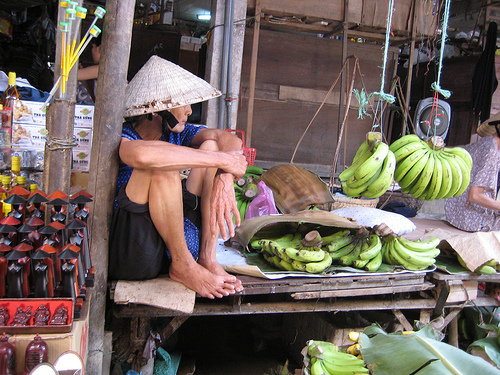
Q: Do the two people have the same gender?
A: No, they are both male and female.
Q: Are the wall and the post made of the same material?
A: Yes, both the wall and the post are made of wood.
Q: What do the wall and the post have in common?
A: The material, both the wall and the post are wooden.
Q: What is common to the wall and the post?
A: The material, both the wall and the post are wooden.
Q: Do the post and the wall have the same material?
A: Yes, both the post and the wall are made of wood.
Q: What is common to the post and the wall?
A: The material, both the post and the wall are wooden.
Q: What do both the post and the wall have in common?
A: The material, both the post and the wall are wooden.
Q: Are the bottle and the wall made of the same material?
A: No, the bottle is made of glass and the wall is made of wood.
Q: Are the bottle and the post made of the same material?
A: No, the bottle is made of glass and the post is made of wood.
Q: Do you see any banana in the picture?
A: Yes, there are bananas.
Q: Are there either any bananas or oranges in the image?
A: Yes, there are bananas.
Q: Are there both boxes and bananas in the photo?
A: Yes, there are both bananas and a box.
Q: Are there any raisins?
A: No, there are no raisins.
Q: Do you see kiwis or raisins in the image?
A: No, there are no raisins or kiwis.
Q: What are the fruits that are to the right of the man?
A: The fruits are bananas.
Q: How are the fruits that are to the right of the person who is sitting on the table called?
A: The fruits are bananas.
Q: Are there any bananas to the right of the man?
A: Yes, there are bananas to the right of the man.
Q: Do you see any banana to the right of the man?
A: Yes, there are bananas to the right of the man.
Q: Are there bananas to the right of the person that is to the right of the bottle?
A: Yes, there are bananas to the right of the man.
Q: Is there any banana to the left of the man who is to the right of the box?
A: No, the bananas are to the right of the man.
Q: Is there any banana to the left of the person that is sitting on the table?
A: No, the bananas are to the right of the man.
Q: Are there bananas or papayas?
A: Yes, there are bananas.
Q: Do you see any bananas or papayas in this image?
A: Yes, there are bananas.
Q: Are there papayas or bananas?
A: Yes, there are bananas.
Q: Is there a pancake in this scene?
A: No, there are no pancakes.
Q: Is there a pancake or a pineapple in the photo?
A: No, there are no pancakes or pineapples.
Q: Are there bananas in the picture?
A: Yes, there are bananas.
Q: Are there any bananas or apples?
A: Yes, there are bananas.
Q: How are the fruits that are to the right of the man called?
A: The fruits are bananas.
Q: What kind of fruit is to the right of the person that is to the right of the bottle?
A: The fruits are bananas.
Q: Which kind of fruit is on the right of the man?
A: The fruits are bananas.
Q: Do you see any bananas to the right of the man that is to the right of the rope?
A: Yes, there are bananas to the right of the man.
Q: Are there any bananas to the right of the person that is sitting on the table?
A: Yes, there are bananas to the right of the man.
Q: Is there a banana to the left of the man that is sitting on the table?
A: No, the bananas are to the right of the man.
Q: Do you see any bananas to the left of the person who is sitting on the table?
A: No, the bananas are to the right of the man.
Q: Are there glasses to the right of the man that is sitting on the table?
A: No, there are bananas to the right of the man.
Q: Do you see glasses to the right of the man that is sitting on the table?
A: No, there are bananas to the right of the man.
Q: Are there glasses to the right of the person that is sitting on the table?
A: No, there are bananas to the right of the man.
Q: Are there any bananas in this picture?
A: Yes, there are bananas.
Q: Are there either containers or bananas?
A: Yes, there are bananas.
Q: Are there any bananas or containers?
A: Yes, there are bananas.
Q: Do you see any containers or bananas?
A: Yes, there are bananas.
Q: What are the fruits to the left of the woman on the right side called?
A: The fruits are bananas.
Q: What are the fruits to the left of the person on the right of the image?
A: The fruits are bananas.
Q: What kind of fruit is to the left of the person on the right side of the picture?
A: The fruits are bananas.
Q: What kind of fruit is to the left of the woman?
A: The fruits are bananas.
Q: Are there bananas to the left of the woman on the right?
A: Yes, there are bananas to the left of the woman.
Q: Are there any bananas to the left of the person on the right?
A: Yes, there are bananas to the left of the woman.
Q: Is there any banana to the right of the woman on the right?
A: No, the bananas are to the left of the woman.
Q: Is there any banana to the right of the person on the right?
A: No, the bananas are to the left of the woman.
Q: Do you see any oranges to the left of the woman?
A: No, there are bananas to the left of the woman.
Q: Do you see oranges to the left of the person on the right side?
A: No, there are bananas to the left of the woman.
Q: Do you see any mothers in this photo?
A: No, there are no mothers.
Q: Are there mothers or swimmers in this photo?
A: No, there are no mothers or swimmers.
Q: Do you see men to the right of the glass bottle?
A: Yes, there is a man to the right of the bottle.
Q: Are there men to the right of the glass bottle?
A: Yes, there is a man to the right of the bottle.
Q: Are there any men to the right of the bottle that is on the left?
A: Yes, there is a man to the right of the bottle.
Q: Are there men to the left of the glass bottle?
A: No, the man is to the right of the bottle.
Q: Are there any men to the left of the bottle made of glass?
A: No, the man is to the right of the bottle.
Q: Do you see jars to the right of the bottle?
A: No, there is a man to the right of the bottle.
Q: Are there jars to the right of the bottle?
A: No, there is a man to the right of the bottle.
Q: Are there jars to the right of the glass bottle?
A: No, there is a man to the right of the bottle.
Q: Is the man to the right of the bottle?
A: Yes, the man is to the right of the bottle.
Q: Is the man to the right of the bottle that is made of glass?
A: Yes, the man is to the right of the bottle.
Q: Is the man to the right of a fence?
A: No, the man is to the right of the bottle.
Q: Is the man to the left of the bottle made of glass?
A: No, the man is to the right of the bottle.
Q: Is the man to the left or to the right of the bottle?
A: The man is to the right of the bottle.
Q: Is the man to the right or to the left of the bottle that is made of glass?
A: The man is to the right of the bottle.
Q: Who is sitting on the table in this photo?
A: The man is sitting on the table.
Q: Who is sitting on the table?
A: The man is sitting on the table.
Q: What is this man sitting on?
A: The man is sitting on the table.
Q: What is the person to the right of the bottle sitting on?
A: The man is sitting on the table.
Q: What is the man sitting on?
A: The man is sitting on the table.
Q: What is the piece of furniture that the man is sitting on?
A: The piece of furniture is a table.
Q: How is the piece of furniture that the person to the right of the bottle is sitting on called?
A: The piece of furniture is a table.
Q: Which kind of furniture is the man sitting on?
A: The man is sitting on the table.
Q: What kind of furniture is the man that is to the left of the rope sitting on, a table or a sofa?
A: The man is sitting on a table.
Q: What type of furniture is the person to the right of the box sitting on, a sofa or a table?
A: The man is sitting on a table.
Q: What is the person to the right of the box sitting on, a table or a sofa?
A: The man is sitting on a table.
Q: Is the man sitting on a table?
A: Yes, the man is sitting on a table.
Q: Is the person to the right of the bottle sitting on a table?
A: Yes, the man is sitting on a table.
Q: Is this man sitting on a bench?
A: No, the man is sitting on a table.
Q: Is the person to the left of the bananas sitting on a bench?
A: No, the man is sitting on a table.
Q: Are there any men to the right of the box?
A: Yes, there is a man to the right of the box.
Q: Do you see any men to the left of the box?
A: No, the man is to the right of the box.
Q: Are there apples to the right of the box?
A: No, there is a man to the right of the box.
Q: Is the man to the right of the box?
A: Yes, the man is to the right of the box.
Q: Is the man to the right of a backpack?
A: No, the man is to the right of the box.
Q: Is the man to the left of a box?
A: No, the man is to the right of a box.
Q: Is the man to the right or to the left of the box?
A: The man is to the right of the box.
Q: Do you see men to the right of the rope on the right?
A: No, the man is to the left of the rope.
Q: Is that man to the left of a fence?
A: No, the man is to the left of the rope.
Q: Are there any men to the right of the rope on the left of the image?
A: Yes, there is a man to the right of the rope.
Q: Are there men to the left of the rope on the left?
A: No, the man is to the right of the rope.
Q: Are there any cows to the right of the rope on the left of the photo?
A: No, there is a man to the right of the rope.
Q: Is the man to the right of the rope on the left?
A: Yes, the man is to the right of the rope.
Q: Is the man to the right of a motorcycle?
A: No, the man is to the right of the rope.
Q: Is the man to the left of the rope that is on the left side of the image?
A: No, the man is to the right of the rope.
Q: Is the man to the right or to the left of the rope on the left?
A: The man is to the right of the rope.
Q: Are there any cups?
A: No, there are no cups.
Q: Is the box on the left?
A: Yes, the box is on the left of the image.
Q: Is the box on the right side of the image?
A: No, the box is on the left of the image.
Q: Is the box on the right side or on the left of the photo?
A: The box is on the left of the image.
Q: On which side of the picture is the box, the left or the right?
A: The box is on the left of the image.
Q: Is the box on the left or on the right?
A: The box is on the left of the image.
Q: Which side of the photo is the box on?
A: The box is on the left of the image.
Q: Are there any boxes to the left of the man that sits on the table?
A: Yes, there is a box to the left of the man.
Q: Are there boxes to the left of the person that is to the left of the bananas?
A: Yes, there is a box to the left of the man.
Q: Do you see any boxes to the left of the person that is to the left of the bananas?
A: Yes, there is a box to the left of the man.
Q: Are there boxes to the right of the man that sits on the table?
A: No, the box is to the left of the man.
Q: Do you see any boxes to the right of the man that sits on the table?
A: No, the box is to the left of the man.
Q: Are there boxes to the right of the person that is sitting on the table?
A: No, the box is to the left of the man.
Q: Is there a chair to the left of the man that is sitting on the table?
A: No, there is a box to the left of the man.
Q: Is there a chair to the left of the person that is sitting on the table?
A: No, there is a box to the left of the man.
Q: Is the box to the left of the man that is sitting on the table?
A: Yes, the box is to the left of the man.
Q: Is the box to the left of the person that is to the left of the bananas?
A: Yes, the box is to the left of the man.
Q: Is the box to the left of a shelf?
A: No, the box is to the left of the man.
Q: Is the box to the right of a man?
A: No, the box is to the left of a man.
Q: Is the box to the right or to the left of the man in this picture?
A: The box is to the left of the man.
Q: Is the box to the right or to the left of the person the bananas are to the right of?
A: The box is to the left of the man.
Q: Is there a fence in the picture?
A: No, there are no fences.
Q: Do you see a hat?
A: Yes, there is a hat.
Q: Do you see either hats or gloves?
A: Yes, there is a hat.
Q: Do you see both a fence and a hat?
A: No, there is a hat but no fences.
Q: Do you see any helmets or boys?
A: No, there are no boys or helmets.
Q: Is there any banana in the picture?
A: Yes, there is a banana.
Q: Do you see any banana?
A: Yes, there is a banana.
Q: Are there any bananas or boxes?
A: Yes, there is a banana.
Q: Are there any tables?
A: Yes, there is a table.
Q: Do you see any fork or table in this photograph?
A: Yes, there is a table.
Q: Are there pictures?
A: No, there are no pictures.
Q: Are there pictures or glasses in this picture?
A: No, there are no pictures or glasses.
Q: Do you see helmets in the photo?
A: No, there are no helmets.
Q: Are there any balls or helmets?
A: No, there are no helmets or balls.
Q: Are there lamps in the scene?
A: No, there are no lamps.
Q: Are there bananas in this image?
A: Yes, there are bananas.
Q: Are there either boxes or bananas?
A: Yes, there are bananas.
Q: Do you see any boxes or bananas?
A: Yes, there are bananas.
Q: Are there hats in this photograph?
A: Yes, there is a hat.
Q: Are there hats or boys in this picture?
A: Yes, there is a hat.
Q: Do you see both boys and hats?
A: No, there is a hat but no boys.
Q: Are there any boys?
A: No, there are no boys.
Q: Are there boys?
A: No, there are no boys.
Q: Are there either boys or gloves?
A: No, there are no boys or gloves.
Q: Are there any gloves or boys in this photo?
A: No, there are no boys or gloves.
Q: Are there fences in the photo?
A: No, there are no fences.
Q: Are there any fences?
A: No, there are no fences.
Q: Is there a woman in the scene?
A: Yes, there is a woman.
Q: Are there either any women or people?
A: Yes, there is a woman.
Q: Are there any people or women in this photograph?
A: Yes, there is a woman.